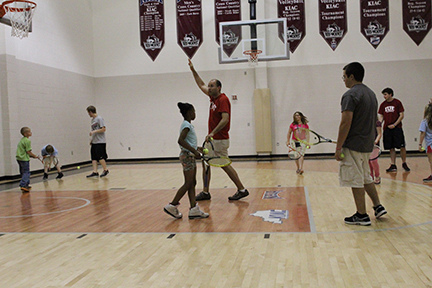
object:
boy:
[13, 127, 42, 194]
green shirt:
[13, 136, 33, 161]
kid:
[39, 143, 64, 180]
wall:
[0, 79, 77, 105]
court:
[0, 157, 430, 287]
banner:
[138, 0, 164, 61]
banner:
[176, 0, 203, 59]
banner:
[319, 0, 347, 48]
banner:
[360, 0, 388, 48]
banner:
[402, 0, 430, 46]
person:
[377, 87, 411, 173]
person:
[165, 101, 209, 223]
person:
[85, 105, 111, 178]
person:
[286, 111, 310, 175]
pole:
[249, 0, 258, 57]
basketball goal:
[244, 48, 260, 63]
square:
[0, 184, 309, 230]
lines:
[302, 189, 319, 236]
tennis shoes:
[344, 214, 370, 226]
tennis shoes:
[163, 203, 185, 219]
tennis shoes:
[298, 169, 305, 175]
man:
[337, 61, 389, 227]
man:
[189, 59, 250, 201]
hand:
[187, 56, 193, 66]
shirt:
[378, 97, 406, 130]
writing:
[382, 104, 394, 113]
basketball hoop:
[217, 17, 288, 64]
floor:
[345, 247, 429, 286]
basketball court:
[0, 16, 430, 284]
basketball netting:
[0, 10, 33, 40]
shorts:
[202, 130, 238, 168]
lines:
[0, 193, 92, 218]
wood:
[0, 241, 236, 259]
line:
[262, 231, 272, 241]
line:
[165, 233, 176, 240]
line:
[76, 233, 90, 240]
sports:
[208, 203, 247, 228]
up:
[187, 56, 208, 96]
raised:
[194, 97, 210, 106]